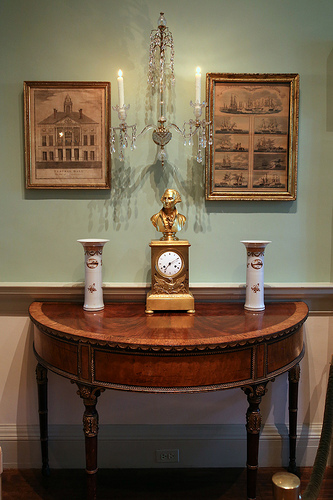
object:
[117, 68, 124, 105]
candle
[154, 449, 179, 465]
outlet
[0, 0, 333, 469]
wall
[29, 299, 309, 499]
table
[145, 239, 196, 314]
clock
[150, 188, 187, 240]
statue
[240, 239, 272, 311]
vase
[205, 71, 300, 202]
picture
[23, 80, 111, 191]
picture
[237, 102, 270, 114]
ships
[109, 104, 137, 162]
candle holder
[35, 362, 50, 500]
leg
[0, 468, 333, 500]
floor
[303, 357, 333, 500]
rope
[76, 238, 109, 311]
vase